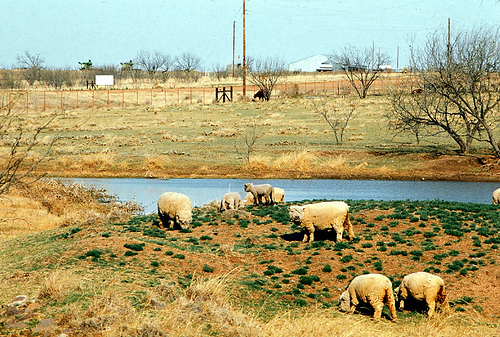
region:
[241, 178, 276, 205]
A baby sheep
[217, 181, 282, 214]
Several sheep drinking at a river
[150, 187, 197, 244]
An unshorn sheep grazing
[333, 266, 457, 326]
Two unshorn sheep grazing side by side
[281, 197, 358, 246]
An unshorn sheep looking at the camera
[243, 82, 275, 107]
A cow or horse grazing in the distance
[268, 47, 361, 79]
A farm building in the distance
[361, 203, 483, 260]
Patchy grass for the sheep to eat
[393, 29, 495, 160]
Barren trees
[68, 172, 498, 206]
A river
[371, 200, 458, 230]
Patchy green grass in dirt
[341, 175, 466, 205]
Water in a ditch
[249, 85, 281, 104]
Cow grazing in the distance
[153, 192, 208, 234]
Sheep eating grass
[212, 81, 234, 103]
Wooden fence door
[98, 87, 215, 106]
Orange fence in the distance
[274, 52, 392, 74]
White farm house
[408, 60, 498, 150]
Trees with no leaves on a water bank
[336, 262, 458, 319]
Two sheep eating green grass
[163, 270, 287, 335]
Tall brown grass in a field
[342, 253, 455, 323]
two sheep grazing together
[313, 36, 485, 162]
barren trees and a fence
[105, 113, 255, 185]
bare grassland and a part of body of water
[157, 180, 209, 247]
a sheep eating alone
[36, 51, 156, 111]
tiny shed far away from sheep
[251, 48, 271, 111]
black unknown animal grazing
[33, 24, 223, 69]
clear blue sky in photo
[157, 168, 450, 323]
sheep eating together in pasture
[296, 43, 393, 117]
big building far from pasture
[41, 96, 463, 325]
feeding the sheep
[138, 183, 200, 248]
a sheep in the field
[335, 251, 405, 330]
a sheep in the field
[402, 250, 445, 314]
a sheep in the field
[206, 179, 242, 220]
a sheep in the field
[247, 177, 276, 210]
a sheep in the field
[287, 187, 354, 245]
a sheep in the field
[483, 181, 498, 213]
a sheep in the field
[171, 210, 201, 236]
the head of a pig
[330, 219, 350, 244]
the leg of a pig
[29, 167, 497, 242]
a small blue river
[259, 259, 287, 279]
a patch of green plants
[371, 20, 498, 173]
a barren tree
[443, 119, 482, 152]
the trunk of a tree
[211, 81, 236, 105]
a dark brown gate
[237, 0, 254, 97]
a brown telephone pole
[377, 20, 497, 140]
the branches of a tree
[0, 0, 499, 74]
a clear blue sky